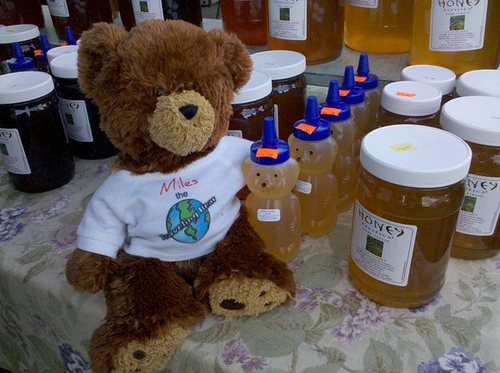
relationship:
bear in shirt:
[65, 18, 293, 371] [62, 132, 275, 264]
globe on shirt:
[164, 197, 212, 245] [76, 136, 252, 261]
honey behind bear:
[0, 35, 110, 193] [65, 20, 296, 372]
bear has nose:
[65, 18, 293, 371] [173, 102, 200, 117]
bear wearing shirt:
[65, 18, 293, 371] [71, 136, 262, 263]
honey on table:
[239, 37, 498, 305] [10, 57, 492, 371]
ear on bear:
[75, 21, 128, 96] [65, 18, 293, 371]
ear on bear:
[210, 29, 252, 91] [65, 18, 293, 371]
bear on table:
[65, 20, 296, 372] [0, 84, 498, 371]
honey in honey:
[2, 70, 78, 198] [0, 70, 75, 193]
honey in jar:
[349, 166, 465, 307] [317, 117, 472, 307]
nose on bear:
[175, 101, 202, 121] [65, 18, 293, 371]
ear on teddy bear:
[76, 21, 118, 96] [65, 13, 295, 369]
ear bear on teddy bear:
[213, 16, 249, 105] [65, 13, 295, 369]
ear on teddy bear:
[209, 29, 252, 89] [65, 13, 295, 369]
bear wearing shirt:
[65, 18, 293, 371] [134, 164, 302, 299]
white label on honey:
[345, 195, 418, 289] [349, 124, 470, 306]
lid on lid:
[250, 116, 290, 166] [251, 113, 289, 163]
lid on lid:
[293, 95, 330, 141] [291, 93, 328, 140]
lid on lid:
[320, 80, 351, 122] [321, 77, 351, 118]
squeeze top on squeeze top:
[333, 63, 366, 103] [338, 65, 365, 104]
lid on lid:
[251, 113, 289, 163] [351, 52, 378, 89]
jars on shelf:
[377, 44, 495, 306] [42, 5, 411, 89]